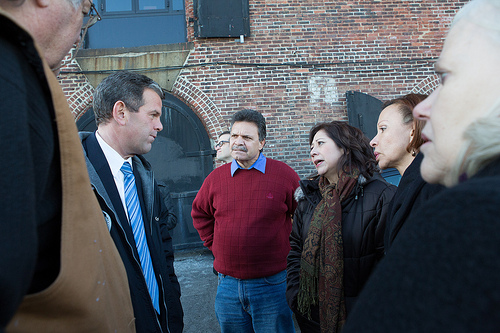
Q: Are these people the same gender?
A: No, they are both male and female.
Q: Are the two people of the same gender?
A: No, they are both male and female.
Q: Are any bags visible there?
A: No, there are no bags.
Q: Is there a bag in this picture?
A: No, there are no bags.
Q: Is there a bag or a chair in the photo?
A: No, there are no bags or chairs.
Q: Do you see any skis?
A: No, there are no skis.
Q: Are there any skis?
A: No, there are no skis.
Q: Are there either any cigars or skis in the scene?
A: No, there are no skis or cigars.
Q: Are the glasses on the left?
A: Yes, the glasses are on the left of the image.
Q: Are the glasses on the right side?
A: No, the glasses are on the left of the image.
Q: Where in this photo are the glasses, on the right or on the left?
A: The glasses are on the left of the image.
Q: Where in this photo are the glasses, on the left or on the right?
A: The glasses are on the left of the image.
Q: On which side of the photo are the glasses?
A: The glasses are on the left of the image.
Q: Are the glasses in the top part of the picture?
A: Yes, the glasses are in the top of the image.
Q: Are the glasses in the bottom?
A: No, the glasses are in the top of the image.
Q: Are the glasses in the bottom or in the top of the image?
A: The glasses are in the top of the image.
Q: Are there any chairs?
A: No, there are no chairs.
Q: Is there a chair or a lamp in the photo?
A: No, there are no chairs or lamps.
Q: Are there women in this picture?
A: Yes, there is a woman.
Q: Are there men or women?
A: Yes, there is a woman.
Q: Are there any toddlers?
A: No, there are no toddlers.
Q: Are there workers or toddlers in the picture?
A: No, there are no toddlers or workers.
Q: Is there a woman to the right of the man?
A: Yes, there is a woman to the right of the man.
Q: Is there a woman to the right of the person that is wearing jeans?
A: Yes, there is a woman to the right of the man.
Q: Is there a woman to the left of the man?
A: No, the woman is to the right of the man.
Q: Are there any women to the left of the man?
A: No, the woman is to the right of the man.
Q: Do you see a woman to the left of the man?
A: No, the woman is to the right of the man.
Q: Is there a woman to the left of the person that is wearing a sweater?
A: No, the woman is to the right of the man.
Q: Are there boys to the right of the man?
A: No, there is a woman to the right of the man.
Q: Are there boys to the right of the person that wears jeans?
A: No, there is a woman to the right of the man.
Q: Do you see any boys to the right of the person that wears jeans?
A: No, there is a woman to the right of the man.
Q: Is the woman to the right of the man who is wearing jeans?
A: Yes, the woman is to the right of the man.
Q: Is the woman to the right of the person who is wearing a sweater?
A: Yes, the woman is to the right of the man.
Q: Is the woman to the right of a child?
A: No, the woman is to the right of the man.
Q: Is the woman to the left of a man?
A: No, the woman is to the right of a man.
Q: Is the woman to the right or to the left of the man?
A: The woman is to the right of the man.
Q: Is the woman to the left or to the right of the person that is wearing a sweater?
A: The woman is to the right of the man.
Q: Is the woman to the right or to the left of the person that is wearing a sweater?
A: The woman is to the right of the man.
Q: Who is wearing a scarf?
A: The woman is wearing a scarf.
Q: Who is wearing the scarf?
A: The woman is wearing a scarf.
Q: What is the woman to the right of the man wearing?
A: The woman is wearing a scarf.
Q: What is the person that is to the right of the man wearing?
A: The woman is wearing a scarf.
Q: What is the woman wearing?
A: The woman is wearing a scarf.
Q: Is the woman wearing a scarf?
A: Yes, the woman is wearing a scarf.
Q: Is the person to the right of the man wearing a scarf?
A: Yes, the woman is wearing a scarf.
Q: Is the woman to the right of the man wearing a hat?
A: No, the woman is wearing a scarf.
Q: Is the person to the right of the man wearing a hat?
A: No, the woman is wearing a scarf.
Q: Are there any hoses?
A: No, there are no hoses.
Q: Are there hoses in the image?
A: No, there are no hoses.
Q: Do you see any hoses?
A: No, there are no hoses.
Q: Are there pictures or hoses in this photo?
A: No, there are no hoses or pictures.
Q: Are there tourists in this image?
A: No, there are no tourists.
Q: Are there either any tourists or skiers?
A: No, there are no tourists or skiers.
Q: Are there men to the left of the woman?
A: Yes, there is a man to the left of the woman.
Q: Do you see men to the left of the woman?
A: Yes, there is a man to the left of the woman.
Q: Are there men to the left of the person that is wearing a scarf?
A: Yes, there is a man to the left of the woman.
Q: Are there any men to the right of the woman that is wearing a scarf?
A: No, the man is to the left of the woman.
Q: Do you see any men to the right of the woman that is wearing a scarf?
A: No, the man is to the left of the woman.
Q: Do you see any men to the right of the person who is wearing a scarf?
A: No, the man is to the left of the woman.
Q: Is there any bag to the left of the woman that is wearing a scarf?
A: No, there is a man to the left of the woman.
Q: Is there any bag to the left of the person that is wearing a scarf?
A: No, there is a man to the left of the woman.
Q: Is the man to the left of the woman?
A: Yes, the man is to the left of the woman.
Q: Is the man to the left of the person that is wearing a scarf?
A: Yes, the man is to the left of the woman.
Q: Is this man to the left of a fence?
A: No, the man is to the left of the woman.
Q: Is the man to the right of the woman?
A: No, the man is to the left of the woman.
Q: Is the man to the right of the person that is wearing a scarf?
A: No, the man is to the left of the woman.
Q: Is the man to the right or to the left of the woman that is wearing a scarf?
A: The man is to the left of the woman.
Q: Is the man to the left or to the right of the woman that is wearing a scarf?
A: The man is to the left of the woman.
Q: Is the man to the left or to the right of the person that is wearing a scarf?
A: The man is to the left of the woman.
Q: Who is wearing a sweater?
A: The man is wearing a sweater.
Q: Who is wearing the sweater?
A: The man is wearing a sweater.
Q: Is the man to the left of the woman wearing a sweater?
A: Yes, the man is wearing a sweater.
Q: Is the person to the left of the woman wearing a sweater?
A: Yes, the man is wearing a sweater.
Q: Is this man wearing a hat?
A: No, the man is wearing a sweater.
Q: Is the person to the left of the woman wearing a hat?
A: No, the man is wearing a sweater.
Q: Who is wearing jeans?
A: The man is wearing jeans.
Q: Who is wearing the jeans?
A: The man is wearing jeans.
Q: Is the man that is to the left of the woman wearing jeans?
A: Yes, the man is wearing jeans.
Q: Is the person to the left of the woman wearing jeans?
A: Yes, the man is wearing jeans.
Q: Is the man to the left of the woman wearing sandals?
A: No, the man is wearing jeans.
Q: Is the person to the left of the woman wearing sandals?
A: No, the man is wearing jeans.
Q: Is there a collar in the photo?
A: Yes, there is a collar.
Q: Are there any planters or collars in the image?
A: Yes, there is a collar.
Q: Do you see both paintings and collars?
A: No, there is a collar but no paintings.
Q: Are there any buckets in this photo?
A: No, there are no buckets.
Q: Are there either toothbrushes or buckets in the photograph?
A: No, there are no buckets or toothbrushes.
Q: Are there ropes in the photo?
A: No, there are no ropes.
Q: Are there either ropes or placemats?
A: No, there are no ropes or placemats.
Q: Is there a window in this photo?
A: Yes, there is a window.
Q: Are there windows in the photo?
A: Yes, there is a window.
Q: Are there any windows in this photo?
A: Yes, there is a window.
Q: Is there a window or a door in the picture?
A: Yes, there is a window.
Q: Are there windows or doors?
A: Yes, there is a window.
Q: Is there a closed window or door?
A: Yes, there is a closed window.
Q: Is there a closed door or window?
A: Yes, there is a closed window.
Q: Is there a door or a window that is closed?
A: Yes, the window is closed.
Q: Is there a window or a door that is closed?
A: Yes, the window is closed.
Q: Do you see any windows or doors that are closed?
A: Yes, the window is closed.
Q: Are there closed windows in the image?
A: Yes, there is a closed window.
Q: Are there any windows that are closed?
A: Yes, there is a window that is closed.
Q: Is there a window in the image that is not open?
A: Yes, there is an closed window.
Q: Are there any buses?
A: No, there are no buses.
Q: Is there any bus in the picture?
A: No, there are no buses.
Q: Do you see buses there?
A: No, there are no buses.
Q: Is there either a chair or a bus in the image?
A: No, there are no buses or chairs.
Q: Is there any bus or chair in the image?
A: No, there are no buses or chairs.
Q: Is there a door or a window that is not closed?
A: No, there is a window but it is closed.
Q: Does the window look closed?
A: Yes, the window is closed.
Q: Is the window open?
A: No, the window is closed.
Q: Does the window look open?
A: No, the window is closed.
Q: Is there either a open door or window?
A: No, there is a window but it is closed.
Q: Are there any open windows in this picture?
A: No, there is a window but it is closed.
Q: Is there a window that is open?
A: No, there is a window but it is closed.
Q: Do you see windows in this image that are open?
A: No, there is a window but it is closed.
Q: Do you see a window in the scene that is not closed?
A: No, there is a window but it is closed.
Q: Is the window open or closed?
A: The window is closed.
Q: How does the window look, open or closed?
A: The window is closed.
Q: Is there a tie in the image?
A: Yes, there is a tie.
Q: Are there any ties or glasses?
A: Yes, there is a tie.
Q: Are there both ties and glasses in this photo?
A: Yes, there are both a tie and glasses.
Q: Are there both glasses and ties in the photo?
A: Yes, there are both a tie and glasses.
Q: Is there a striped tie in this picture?
A: Yes, there is a striped tie.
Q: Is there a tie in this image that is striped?
A: Yes, there is a tie that is striped.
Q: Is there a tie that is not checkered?
A: Yes, there is a striped tie.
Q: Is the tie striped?
A: Yes, the tie is striped.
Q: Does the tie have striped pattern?
A: Yes, the tie is striped.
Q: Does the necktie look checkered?
A: No, the necktie is striped.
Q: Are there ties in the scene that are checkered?
A: No, there is a tie but it is striped.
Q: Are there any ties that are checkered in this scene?
A: No, there is a tie but it is striped.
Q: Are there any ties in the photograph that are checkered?
A: No, there is a tie but it is striped.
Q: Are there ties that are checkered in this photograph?
A: No, there is a tie but it is striped.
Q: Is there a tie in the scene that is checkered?
A: No, there is a tie but it is striped.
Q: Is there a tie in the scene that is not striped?
A: No, there is a tie but it is striped.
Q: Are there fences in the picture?
A: No, there are no fences.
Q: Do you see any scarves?
A: Yes, there is a scarf.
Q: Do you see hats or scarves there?
A: Yes, there is a scarf.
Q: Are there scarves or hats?
A: Yes, there is a scarf.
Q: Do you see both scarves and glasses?
A: Yes, there are both a scarf and glasses.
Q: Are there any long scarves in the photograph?
A: Yes, there is a long scarf.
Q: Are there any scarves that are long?
A: Yes, there is a scarf that is long.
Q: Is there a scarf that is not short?
A: Yes, there is a long scarf.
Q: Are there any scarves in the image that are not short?
A: Yes, there is a long scarf.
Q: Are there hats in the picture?
A: No, there are no hats.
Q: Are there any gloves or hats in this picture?
A: No, there are no hats or gloves.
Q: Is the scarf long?
A: Yes, the scarf is long.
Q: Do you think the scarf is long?
A: Yes, the scarf is long.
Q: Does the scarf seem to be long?
A: Yes, the scarf is long.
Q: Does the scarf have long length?
A: Yes, the scarf is long.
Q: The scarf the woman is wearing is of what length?
A: The scarf is long.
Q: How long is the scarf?
A: The scarf is long.